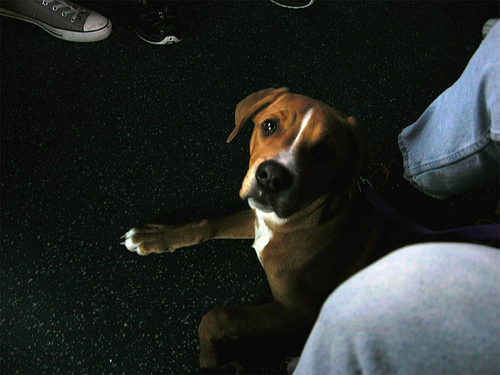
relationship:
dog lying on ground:
[118, 83, 499, 374] [0, 0, 499, 374]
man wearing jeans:
[287, 16, 498, 373] [289, 19, 497, 374]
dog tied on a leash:
[118, 83, 499, 374] [357, 176, 499, 244]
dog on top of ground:
[118, 83, 499, 374] [0, 0, 499, 374]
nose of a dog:
[254, 158, 295, 196] [118, 83, 499, 374]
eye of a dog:
[259, 116, 280, 139] [118, 83, 499, 374]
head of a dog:
[225, 85, 370, 226] [118, 83, 499, 374]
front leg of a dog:
[196, 298, 306, 374] [118, 83, 499, 374]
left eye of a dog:
[312, 137, 335, 165] [118, 83, 499, 374]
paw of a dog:
[118, 220, 172, 256] [118, 83, 499, 374]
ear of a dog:
[226, 85, 293, 145] [118, 83, 499, 374]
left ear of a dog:
[329, 111, 369, 217] [118, 83, 499, 374]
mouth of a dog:
[242, 190, 277, 217] [118, 83, 499, 374]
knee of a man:
[290, 240, 498, 373] [287, 16, 498, 373]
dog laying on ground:
[118, 83, 499, 374] [0, 0, 499, 374]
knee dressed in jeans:
[290, 240, 498, 373] [289, 19, 497, 374]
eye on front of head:
[259, 116, 280, 139] [225, 85, 370, 226]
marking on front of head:
[285, 103, 317, 155] [225, 85, 370, 226]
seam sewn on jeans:
[402, 130, 498, 181] [289, 19, 497, 374]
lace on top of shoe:
[39, 0, 91, 24] [0, 0, 114, 43]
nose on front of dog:
[254, 158, 295, 196] [118, 83, 499, 374]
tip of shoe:
[82, 7, 113, 45] [0, 0, 114, 43]